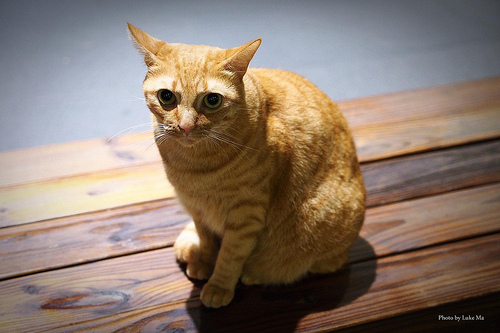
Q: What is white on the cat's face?
A: Whiskers.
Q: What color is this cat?
A: Tan.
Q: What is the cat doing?
A: Sitting.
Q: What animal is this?
A: A cat.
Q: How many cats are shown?
A: One.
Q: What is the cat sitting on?
A: A bench.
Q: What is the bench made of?
A: Wood.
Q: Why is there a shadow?
A: Light is shining on the cat.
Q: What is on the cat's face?
A: Whiskers.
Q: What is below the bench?
A: A sidewalk.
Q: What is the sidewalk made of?
A: Concrete.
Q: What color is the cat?
A: Golden.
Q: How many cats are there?
A: One.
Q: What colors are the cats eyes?
A: Green and black.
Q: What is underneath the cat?
A: Wood.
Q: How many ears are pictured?
A: Two.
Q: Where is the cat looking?
A: At the camera.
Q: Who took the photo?
A: Luke Ma.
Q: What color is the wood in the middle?
A: Dark brown.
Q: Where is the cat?
A: On the table.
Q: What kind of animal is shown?
A: Cat.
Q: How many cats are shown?
A: One.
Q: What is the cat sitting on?
A: Boards.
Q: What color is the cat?
A: Orange.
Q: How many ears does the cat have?
A: Two.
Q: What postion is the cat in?
A: Sitting.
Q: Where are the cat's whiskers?
A: On the cat's face.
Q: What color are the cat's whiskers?
A: White.